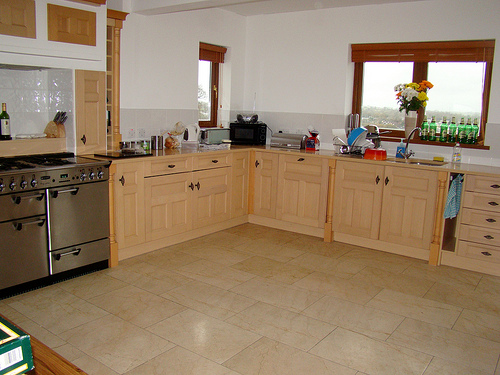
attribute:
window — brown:
[349, 37, 499, 160]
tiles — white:
[16, 82, 42, 117]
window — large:
[344, 44, 499, 139]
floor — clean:
[161, 289, 403, 357]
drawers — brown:
[149, 152, 237, 179]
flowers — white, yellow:
[400, 74, 427, 116]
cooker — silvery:
[1, 149, 111, 295]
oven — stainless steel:
[0, 151, 112, 298]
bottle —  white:
[2, 101, 10, 137]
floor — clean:
[0, 221, 499, 373]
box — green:
[0, 318, 37, 373]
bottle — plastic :
[439, 124, 464, 175]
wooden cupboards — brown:
[94, 142, 458, 262]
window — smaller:
[197, 57, 212, 120]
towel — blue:
[440, 170, 464, 220]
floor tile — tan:
[5, 216, 495, 373]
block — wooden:
[44, 120, 65, 138]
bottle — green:
[469, 118, 481, 141]